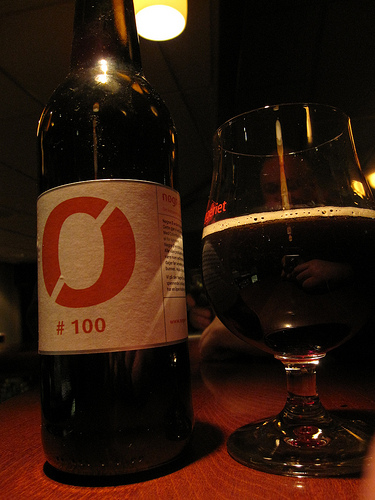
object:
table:
[0, 326, 375, 500]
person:
[249, 144, 366, 295]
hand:
[287, 259, 353, 288]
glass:
[201, 102, 375, 478]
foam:
[202, 205, 375, 236]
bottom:
[229, 331, 375, 366]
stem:
[274, 355, 326, 416]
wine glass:
[199, 100, 373, 477]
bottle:
[34, 0, 192, 473]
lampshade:
[129, 0, 190, 44]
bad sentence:
[198, 316, 253, 365]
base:
[226, 401, 369, 478]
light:
[131, 1, 187, 41]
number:
[36, 178, 189, 356]